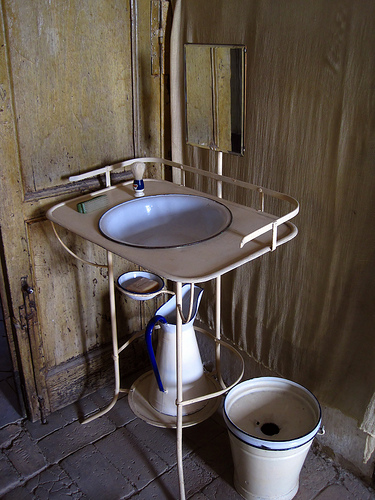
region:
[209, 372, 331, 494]
pail on the floor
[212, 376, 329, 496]
white pail on the floor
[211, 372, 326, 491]
metal pail on the floor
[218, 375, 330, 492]
white metal pail on the floor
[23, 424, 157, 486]
concrete floor in view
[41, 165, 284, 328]
small sink area in view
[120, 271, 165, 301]
small bar of soap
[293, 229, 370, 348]
patch of curtain area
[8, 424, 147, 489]
patch of concrete floor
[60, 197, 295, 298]
small washbowl area in view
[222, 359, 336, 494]
This is a basin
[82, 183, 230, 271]
This is a bowl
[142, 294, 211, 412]
white pitcher under sink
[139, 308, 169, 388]
blue handle of white pitcher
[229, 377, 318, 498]
trashcan beside sink stand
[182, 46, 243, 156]
mirror above sink stand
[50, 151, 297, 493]
stand sink is in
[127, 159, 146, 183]
light bulb on sink stand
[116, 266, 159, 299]
soap dish under sink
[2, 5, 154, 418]
worn wood wall beside sink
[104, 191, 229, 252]
white bowl of sink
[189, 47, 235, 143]
wall reflected in mirror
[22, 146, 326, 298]
This is a water sink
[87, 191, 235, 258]
a white bathroom sink.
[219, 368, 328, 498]
a bucket in a bathroom.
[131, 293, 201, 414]
A blue and white glass object.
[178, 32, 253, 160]
a mirror on the side of a wall.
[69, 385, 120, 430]
a metal bar support for a sink.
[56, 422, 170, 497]
a brick on the floor.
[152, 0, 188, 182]
A corner in a room.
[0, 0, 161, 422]
A door in a room.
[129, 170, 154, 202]
A faucet on a sink.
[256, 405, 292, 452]
A hole in a bucket.